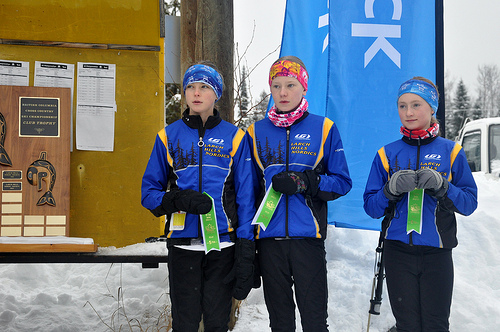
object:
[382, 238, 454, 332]
pants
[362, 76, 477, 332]
girl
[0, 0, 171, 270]
school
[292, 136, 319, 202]
ground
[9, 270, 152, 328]
snow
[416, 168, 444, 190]
glove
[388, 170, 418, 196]
glove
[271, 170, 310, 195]
glove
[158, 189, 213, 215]
glove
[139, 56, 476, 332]
three girls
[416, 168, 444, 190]
hand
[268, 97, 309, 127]
scarf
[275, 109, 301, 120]
neck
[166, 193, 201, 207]
mitten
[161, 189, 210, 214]
girl's hand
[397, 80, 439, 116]
blue bandana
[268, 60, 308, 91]
bandanna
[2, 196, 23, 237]
plaque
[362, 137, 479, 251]
jacket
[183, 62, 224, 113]
head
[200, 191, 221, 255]
award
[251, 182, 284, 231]
award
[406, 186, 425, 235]
award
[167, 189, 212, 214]
hand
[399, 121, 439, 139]
scarf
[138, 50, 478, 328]
group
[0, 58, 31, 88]
posting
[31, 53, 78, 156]
posting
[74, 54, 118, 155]
posting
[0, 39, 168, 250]
wall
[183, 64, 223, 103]
bandana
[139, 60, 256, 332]
girl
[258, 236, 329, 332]
pants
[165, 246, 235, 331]
pants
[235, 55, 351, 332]
girl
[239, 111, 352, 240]
jacket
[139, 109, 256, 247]
jacket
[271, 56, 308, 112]
head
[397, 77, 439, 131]
head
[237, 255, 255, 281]
mitten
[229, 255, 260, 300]
hand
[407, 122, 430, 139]
neck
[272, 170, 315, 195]
hand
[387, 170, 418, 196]
hand